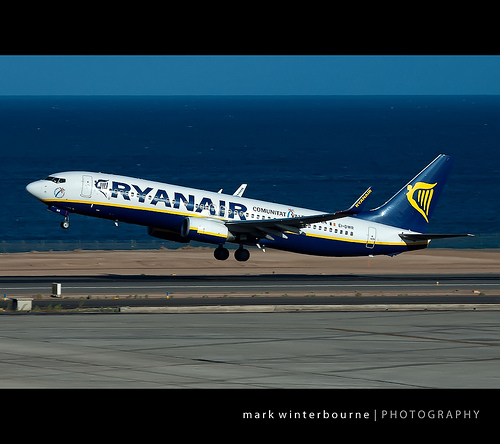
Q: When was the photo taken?
A: Daytime.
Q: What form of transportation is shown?
A: Plane.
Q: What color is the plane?
A: White and blue.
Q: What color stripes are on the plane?
A: Yellow.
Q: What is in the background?
A: Water.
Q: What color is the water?
A: Blue.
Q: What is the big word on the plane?
A: RYANAIR.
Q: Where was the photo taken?
A: At an airport.